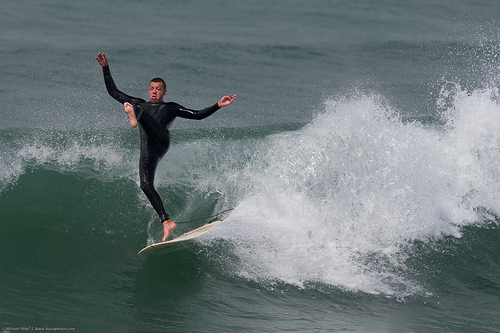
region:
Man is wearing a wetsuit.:
[92, 45, 239, 245]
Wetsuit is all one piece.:
[83, 62, 233, 241]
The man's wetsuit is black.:
[85, 61, 236, 241]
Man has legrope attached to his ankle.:
[150, 200, 250, 237]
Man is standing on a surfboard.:
[90, 45, 275, 265]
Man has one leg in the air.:
[112, 90, 182, 165]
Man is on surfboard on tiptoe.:
[135, 185, 185, 245]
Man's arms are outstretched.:
[75, 45, 240, 116]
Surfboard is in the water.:
[117, 197, 271, 259]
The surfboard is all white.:
[114, 207, 247, 264]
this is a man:
[91, 64, 229, 234]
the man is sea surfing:
[86, 64, 221, 244]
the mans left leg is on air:
[116, 102, 168, 134]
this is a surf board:
[138, 232, 223, 252]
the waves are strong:
[240, 103, 494, 270]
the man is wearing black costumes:
[137, 109, 177, 174]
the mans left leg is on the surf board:
[158, 217, 173, 244]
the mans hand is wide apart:
[181, 83, 251, 120]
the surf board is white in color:
[138, 235, 194, 260]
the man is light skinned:
[131, 113, 133, 120]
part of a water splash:
[296, 145, 403, 248]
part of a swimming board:
[147, 232, 196, 255]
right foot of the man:
[158, 215, 183, 241]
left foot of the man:
[118, 107, 148, 131]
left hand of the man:
[209, 86, 241, 108]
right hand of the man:
[84, 46, 119, 68]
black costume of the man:
[142, 135, 167, 157]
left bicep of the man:
[174, 105, 194, 119]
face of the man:
[142, 77, 162, 98]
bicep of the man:
[107, 85, 134, 106]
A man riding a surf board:
[90, 47, 243, 266]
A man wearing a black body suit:
[88, 47, 235, 236]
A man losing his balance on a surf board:
[76, 48, 256, 260]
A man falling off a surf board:
[77, 40, 248, 280]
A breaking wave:
[247, 111, 499, 307]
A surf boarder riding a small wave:
[5, 142, 499, 332]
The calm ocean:
[0, 0, 372, 53]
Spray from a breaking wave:
[402, 20, 498, 109]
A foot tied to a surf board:
[128, 206, 240, 263]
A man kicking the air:
[96, 48, 242, 159]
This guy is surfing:
[48, 26, 471, 298]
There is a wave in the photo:
[20, 30, 487, 319]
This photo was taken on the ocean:
[35, 13, 497, 309]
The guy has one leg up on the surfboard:
[61, 31, 316, 301]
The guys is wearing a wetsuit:
[38, 27, 374, 312]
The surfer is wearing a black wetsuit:
[74, 36, 356, 296]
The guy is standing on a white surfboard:
[82, 32, 281, 293]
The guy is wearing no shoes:
[53, 37, 294, 300]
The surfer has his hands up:
[20, 29, 367, 307]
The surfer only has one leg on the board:
[70, 36, 289, 330]